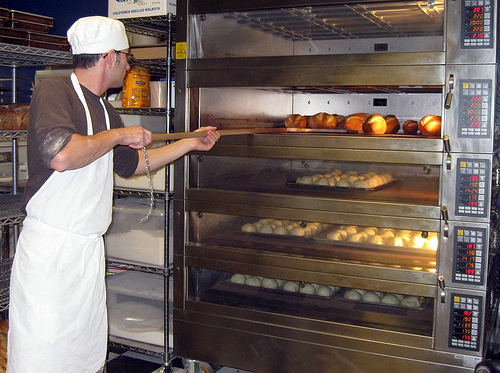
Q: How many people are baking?
A: One.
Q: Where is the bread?
A: Oven.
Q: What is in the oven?
A: Rolls.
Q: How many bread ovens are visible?
A: Five.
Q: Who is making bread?
A: Baker.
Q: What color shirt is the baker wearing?
A: Brown.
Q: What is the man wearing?
A: Apron and hat.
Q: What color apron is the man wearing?
A: White.